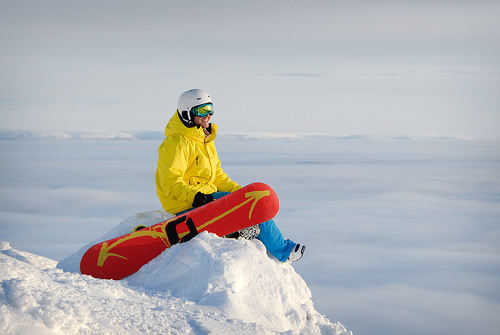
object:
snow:
[0, 209, 354, 335]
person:
[156, 85, 305, 265]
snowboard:
[78, 181, 280, 284]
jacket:
[156, 111, 240, 216]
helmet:
[176, 87, 215, 128]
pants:
[211, 190, 296, 264]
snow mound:
[55, 210, 351, 335]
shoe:
[281, 240, 304, 263]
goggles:
[192, 103, 218, 118]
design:
[89, 189, 272, 266]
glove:
[190, 193, 213, 208]